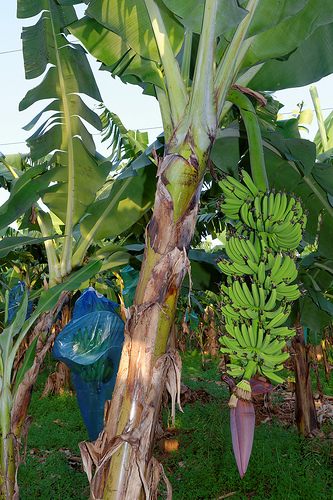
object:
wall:
[256, 90, 270, 98]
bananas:
[239, 173, 258, 198]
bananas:
[264, 308, 287, 330]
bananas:
[253, 188, 263, 220]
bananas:
[261, 370, 284, 385]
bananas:
[72, 328, 85, 355]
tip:
[225, 393, 255, 478]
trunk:
[88, 165, 205, 483]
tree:
[54, 0, 332, 498]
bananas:
[96, 322, 107, 340]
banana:
[255, 321, 263, 348]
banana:
[247, 322, 255, 347]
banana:
[240, 278, 255, 306]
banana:
[223, 234, 245, 265]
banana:
[232, 320, 246, 348]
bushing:
[159, 394, 242, 499]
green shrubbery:
[0, 0, 163, 498]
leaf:
[0, 232, 69, 260]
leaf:
[0, 150, 60, 274]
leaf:
[12, 328, 41, 396]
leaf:
[0, 274, 29, 377]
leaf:
[209, 117, 332, 257]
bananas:
[268, 187, 274, 221]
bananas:
[94, 360, 107, 383]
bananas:
[237, 197, 250, 229]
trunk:
[88, 142, 212, 499]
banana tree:
[62, 0, 332, 499]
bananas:
[78, 365, 86, 383]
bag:
[51, 284, 125, 442]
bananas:
[272, 189, 288, 221]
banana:
[230, 184, 254, 203]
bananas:
[223, 367, 247, 379]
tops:
[54, 20, 333, 128]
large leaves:
[16, 0, 114, 276]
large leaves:
[55, 0, 185, 116]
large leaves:
[226, 0, 333, 107]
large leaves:
[71, 130, 166, 265]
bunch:
[246, 186, 307, 253]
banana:
[252, 194, 261, 215]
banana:
[245, 320, 255, 350]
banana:
[232, 276, 250, 310]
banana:
[243, 255, 259, 275]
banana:
[278, 289, 305, 304]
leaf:
[90, 93, 149, 175]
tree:
[0, 0, 164, 498]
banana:
[238, 167, 258, 198]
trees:
[188, 305, 212, 370]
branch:
[226, 89, 271, 190]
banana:
[263, 214, 272, 233]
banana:
[246, 207, 257, 230]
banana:
[257, 233, 269, 252]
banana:
[242, 235, 260, 265]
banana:
[254, 262, 266, 285]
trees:
[39, 295, 75, 399]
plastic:
[4, 279, 36, 335]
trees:
[284, 293, 328, 454]